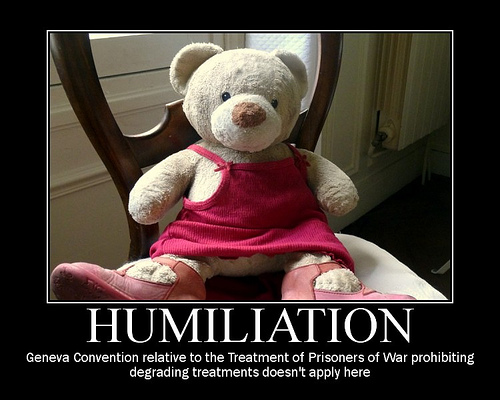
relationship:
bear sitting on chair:
[47, 39, 416, 304] [347, 242, 415, 284]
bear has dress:
[47, 39, 416, 304] [208, 155, 305, 250]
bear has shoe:
[47, 39, 416, 304] [277, 263, 419, 301]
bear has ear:
[47, 39, 416, 304] [165, 43, 198, 98]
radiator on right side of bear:
[370, 30, 452, 153] [47, 39, 416, 304]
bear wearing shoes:
[47, 39, 416, 304] [39, 252, 427, 300]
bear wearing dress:
[47, 39, 416, 304] [208, 155, 305, 250]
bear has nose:
[155, 39, 343, 187] [229, 104, 268, 130]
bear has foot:
[155, 39, 343, 187] [307, 276, 360, 290]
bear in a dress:
[155, 39, 343, 187] [208, 155, 305, 250]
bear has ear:
[155, 39, 343, 187] [165, 43, 198, 98]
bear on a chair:
[155, 39, 343, 187] [347, 242, 415, 284]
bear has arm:
[155, 39, 343, 187] [130, 160, 198, 210]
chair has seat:
[347, 242, 415, 284] [358, 248, 385, 275]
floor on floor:
[403, 197, 435, 246] [339, 173, 452, 300]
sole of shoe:
[68, 272, 85, 294] [277, 263, 419, 301]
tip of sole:
[406, 294, 416, 303] [68, 272, 85, 294]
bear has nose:
[47, 39, 416, 304] [229, 104, 268, 130]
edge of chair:
[437, 292, 450, 303] [347, 242, 415, 284]